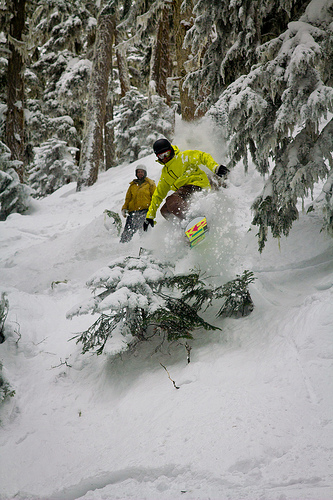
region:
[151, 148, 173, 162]
person wearing silver sunglasses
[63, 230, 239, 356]
tree branch in the snow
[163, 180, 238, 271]
man snow boarding down the mountain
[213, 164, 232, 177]
man wearing black gloves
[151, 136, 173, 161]
man wearing a black helmet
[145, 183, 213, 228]
man wearing brown pants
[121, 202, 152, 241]
man wearing black pants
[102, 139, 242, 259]
two men on a mountain top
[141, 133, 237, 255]
person snowboarding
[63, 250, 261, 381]
snow covered bush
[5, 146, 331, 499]
snow covered hill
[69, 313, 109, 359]
pine needles on stem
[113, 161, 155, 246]
person standing in snow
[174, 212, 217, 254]
orange and green designs on bottom of snow board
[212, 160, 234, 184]
black glove on hand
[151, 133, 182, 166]
black hat on skier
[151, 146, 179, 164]
goggles on skier's eyes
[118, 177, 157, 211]
yellow winter jacket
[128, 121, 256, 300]
a snowboarder doing a jump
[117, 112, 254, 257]
a snowboarder in the air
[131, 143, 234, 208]
a bright yellow jacket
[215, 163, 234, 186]
black gloves on the hands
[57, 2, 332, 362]
snow on the tree branches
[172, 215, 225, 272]
a K2 snowboard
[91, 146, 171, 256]
a man watching the snowboarder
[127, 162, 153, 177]
white hat on head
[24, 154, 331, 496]
snow covers the ground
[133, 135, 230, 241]
person's jacket is yellow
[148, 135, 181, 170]
person is wearing goggles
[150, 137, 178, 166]
person's hat is black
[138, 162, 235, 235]
person's gloves are black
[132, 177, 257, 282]
snow being thrown in air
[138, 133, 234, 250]
man is snowboarding downhill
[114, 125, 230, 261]
man is watching other man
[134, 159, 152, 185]
man wearing a hat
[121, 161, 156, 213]
man's jacket is yellowish brown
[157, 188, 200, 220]
man's pants are brown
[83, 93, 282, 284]
a snowboarder in the air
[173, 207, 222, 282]
a K2 snowboard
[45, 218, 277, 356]
a tree branch with snow on it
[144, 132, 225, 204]
a yellow and black jacket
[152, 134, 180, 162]
a black hat on head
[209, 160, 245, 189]
black gloves on hand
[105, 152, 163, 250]
a man standing and watching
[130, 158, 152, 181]
a white hat on head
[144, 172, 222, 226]
brown snow pants on snowboarder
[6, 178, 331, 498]
snow covers the ground